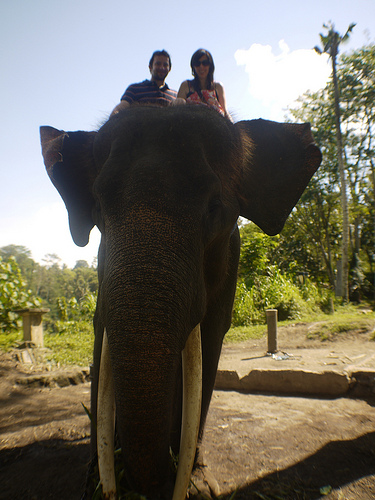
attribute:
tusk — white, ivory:
[171, 321, 202, 498]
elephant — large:
[30, 80, 306, 496]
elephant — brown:
[40, 100, 322, 499]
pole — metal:
[255, 306, 295, 363]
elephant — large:
[32, 114, 317, 402]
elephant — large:
[203, 117, 317, 237]